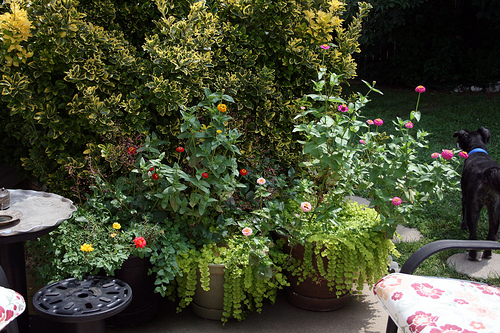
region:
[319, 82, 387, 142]
pink flowers on bush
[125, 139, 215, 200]
red flowers on bush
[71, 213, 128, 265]
yellow flowers on bush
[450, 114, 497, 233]
black dog with blue collar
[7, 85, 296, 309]
bushes in clay pot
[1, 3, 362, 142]
green and yellow leaves on bush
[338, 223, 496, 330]
flowers on patio chair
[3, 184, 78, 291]
black out door table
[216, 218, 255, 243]
pink flowers on bush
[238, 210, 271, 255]
pink flowers on bush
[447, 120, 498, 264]
a dog near pink roses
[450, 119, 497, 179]
dog wears a collar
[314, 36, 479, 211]
pink roses on a tree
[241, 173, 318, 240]
three pink roses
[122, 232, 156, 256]
a red flower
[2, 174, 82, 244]
a table next to flowers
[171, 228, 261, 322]
a pot with green leaves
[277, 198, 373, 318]
a pot color brown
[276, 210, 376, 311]
green plants on a pot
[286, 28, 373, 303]
pink flowers on a pot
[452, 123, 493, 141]
ears of a dog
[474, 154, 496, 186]
tail of a dog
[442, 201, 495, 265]
legs of a dog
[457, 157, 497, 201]
body of a dog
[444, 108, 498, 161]
head of a dog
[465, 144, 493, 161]
collar of a dog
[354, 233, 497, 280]
arm rest of a chair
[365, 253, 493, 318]
cushion of a chair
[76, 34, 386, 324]
outdoor plants on the floor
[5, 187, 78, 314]
a table on the lawn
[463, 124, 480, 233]
Dog in the back next to a green tree.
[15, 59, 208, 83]
Dog in the back next to a green tree.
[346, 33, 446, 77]
Dog in the back next to a green tree.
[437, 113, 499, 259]
dog is looking at the grass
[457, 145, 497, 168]
blue collar on the dog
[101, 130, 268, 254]
red flowers in plants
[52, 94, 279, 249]
yellow flowers in plants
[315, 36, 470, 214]
pink flowers in plants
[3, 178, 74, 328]
table next to the plants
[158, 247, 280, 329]
plant leaves hanging off the pot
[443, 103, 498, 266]
dog standing on concrete pavement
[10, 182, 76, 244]
light shining on table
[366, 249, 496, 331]
flowers on chair cushion